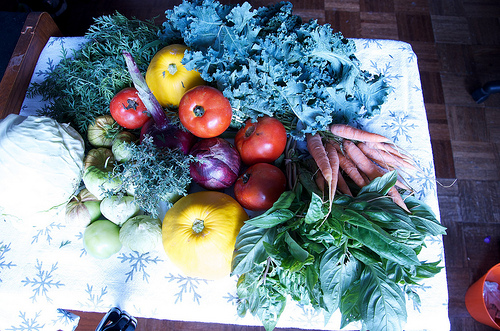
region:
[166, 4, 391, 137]
spinach in bunch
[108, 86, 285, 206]
tomatoes all round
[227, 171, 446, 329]
kale full and washed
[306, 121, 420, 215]
carrots medium in size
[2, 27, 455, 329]
a square platter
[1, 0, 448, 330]
table holding everything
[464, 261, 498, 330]
a bucket on floor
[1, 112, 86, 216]
a cabbage on platter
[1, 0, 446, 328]
a platter of vegetables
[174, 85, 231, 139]
a red tomatoe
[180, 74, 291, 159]
two red tomatoes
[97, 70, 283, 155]
three red tomatoes next to other vegetables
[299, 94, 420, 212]
orange carrots near green leafy vegetables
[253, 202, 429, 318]
a bunch of green leafy vegetables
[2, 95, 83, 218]
a cabbage on the counter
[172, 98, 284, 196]
tomatoes and red onions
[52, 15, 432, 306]
vegetables on a cloth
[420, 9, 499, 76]
brown floor tiles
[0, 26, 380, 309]
vegetables on a cutting board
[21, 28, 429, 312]
food on top of board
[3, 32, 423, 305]
food on a table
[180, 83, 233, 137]
red tomato on table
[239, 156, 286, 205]
red tomato on table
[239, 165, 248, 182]
green stem from tomato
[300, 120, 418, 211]
orange carrots on trey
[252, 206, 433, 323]
green leaves on board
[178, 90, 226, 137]
Nice red ripe tomato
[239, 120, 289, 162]
Nice red ripe tomato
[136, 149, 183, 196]
Nice green broccoli crown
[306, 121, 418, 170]
Part of bunch of carrots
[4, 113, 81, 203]
Part of fresh cabbage head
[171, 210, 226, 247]
Part of yellow squash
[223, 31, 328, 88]
Part of fresh green vegetable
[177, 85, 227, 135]
a tomato is red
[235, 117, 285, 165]
a tomato is red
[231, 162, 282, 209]
a tomato is red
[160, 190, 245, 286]
a bright yellow squash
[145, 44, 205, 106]
a bright yellow squash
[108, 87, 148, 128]
a tomato is red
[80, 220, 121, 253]
a tomato is green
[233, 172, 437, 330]
fresh greens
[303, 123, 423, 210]
a bunch of carrots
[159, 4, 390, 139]
a loose bunch of a kale